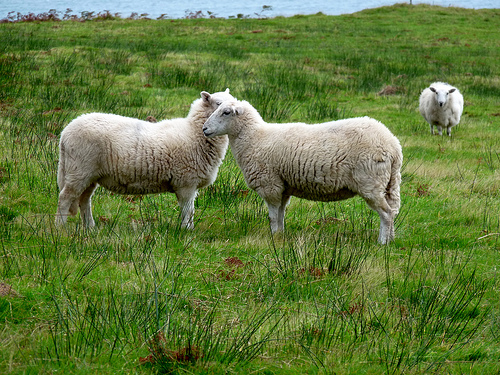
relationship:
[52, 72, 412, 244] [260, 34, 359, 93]
sheep in field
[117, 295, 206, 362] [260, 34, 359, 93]
bushes in field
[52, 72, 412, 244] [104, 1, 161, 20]
sheep behind ocean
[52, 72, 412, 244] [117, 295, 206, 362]
sheep on bushes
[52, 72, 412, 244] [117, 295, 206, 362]
sheep near bushes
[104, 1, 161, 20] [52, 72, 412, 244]
ocean next to sheep